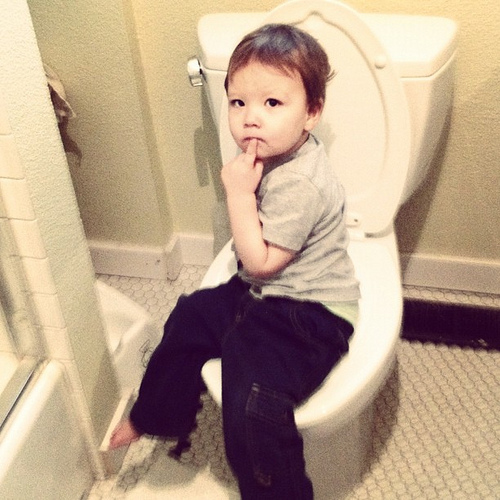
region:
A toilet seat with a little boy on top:
[161, 75, 396, 398]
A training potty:
[105, 272, 165, 358]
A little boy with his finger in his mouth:
[192, 42, 332, 207]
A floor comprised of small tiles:
[390, 405, 485, 485]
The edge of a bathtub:
[0, 350, 90, 485]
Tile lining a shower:
[15, 205, 45, 351]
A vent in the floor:
[411, 287, 496, 339]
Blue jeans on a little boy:
[133, 261, 344, 476]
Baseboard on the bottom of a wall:
[113, 231, 185, 280]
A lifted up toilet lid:
[225, 5, 403, 246]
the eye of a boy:
[263, 93, 290, 113]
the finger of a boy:
[239, 134, 264, 165]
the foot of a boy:
[94, 411, 165, 454]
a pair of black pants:
[111, 271, 359, 498]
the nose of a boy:
[239, 102, 268, 130]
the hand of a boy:
[210, 134, 278, 193]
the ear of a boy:
[300, 83, 330, 134]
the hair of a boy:
[216, 20, 333, 114]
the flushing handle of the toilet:
[180, 51, 212, 89]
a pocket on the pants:
[242, 376, 302, 490]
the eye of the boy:
[261, 91, 282, 111]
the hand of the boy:
[216, 136, 276, 193]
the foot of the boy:
[102, 407, 190, 451]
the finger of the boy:
[243, 136, 261, 161]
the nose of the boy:
[242, 100, 262, 130]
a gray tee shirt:
[225, 125, 364, 313]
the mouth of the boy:
[240, 130, 271, 147]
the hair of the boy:
[219, 20, 338, 115]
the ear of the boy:
[299, 94, 330, 137]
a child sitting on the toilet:
[109, 9, 424, 466]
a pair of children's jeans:
[88, 277, 355, 498]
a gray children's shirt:
[204, 136, 367, 314]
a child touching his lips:
[198, 27, 333, 192]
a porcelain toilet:
[182, 19, 443, 416]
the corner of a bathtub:
[0, 200, 102, 477]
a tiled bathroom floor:
[80, 293, 439, 496]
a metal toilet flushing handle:
[170, 42, 209, 104]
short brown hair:
[215, 18, 342, 113]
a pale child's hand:
[210, 131, 272, 196]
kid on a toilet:
[139, 30, 409, 357]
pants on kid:
[103, 303, 355, 485]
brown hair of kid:
[216, 23, 358, 97]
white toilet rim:
[338, 289, 425, 404]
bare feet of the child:
[103, 403, 163, 457]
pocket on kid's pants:
[273, 296, 339, 362]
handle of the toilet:
[176, 53, 212, 101]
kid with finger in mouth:
[218, 41, 380, 176]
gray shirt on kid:
[263, 136, 378, 263]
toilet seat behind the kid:
[348, 15, 425, 191]